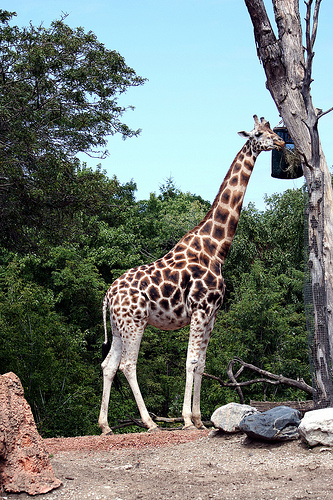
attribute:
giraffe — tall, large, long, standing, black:
[68, 90, 293, 470]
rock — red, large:
[188, 360, 317, 469]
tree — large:
[260, 24, 312, 122]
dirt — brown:
[94, 407, 179, 457]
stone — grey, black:
[188, 395, 246, 445]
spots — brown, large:
[188, 202, 240, 276]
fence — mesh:
[196, 331, 302, 427]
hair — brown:
[239, 104, 283, 141]